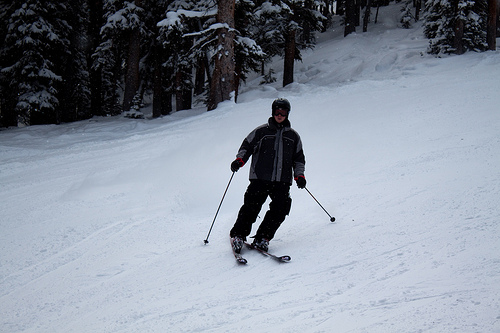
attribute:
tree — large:
[146, 1, 176, 114]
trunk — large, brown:
[283, 20, 298, 83]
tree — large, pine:
[200, 13, 225, 110]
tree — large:
[170, 0, 198, 113]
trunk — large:
[81, 6, 112, 115]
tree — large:
[53, 4, 83, 120]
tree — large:
[1, 6, 29, 135]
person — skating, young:
[204, 97, 305, 267]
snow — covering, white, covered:
[4, 35, 499, 332]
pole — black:
[197, 169, 236, 242]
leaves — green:
[94, 9, 186, 81]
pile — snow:
[282, 81, 309, 95]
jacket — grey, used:
[233, 121, 305, 186]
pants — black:
[232, 183, 296, 243]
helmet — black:
[272, 97, 292, 116]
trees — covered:
[106, 6, 268, 119]